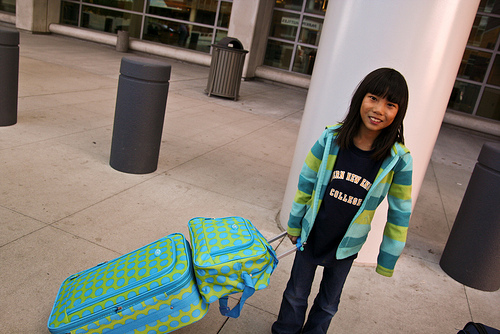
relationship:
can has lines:
[205, 34, 245, 99] [212, 51, 241, 96]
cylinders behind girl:
[108, 57, 165, 175] [268, 65, 414, 334]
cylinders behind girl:
[437, 139, 499, 294] [268, 65, 414, 334]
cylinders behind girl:
[1, 28, 21, 126] [268, 65, 414, 334]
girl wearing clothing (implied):
[268, 65, 414, 334] [286, 124, 413, 277]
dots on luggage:
[48, 216, 278, 332] [42, 208, 311, 332]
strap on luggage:
[219, 291, 263, 323] [43, 196, 326, 332]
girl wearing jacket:
[268, 65, 414, 334] [276, 125, 434, 282]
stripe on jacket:
[385, 207, 413, 226] [287, 122, 412, 275]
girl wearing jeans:
[250, 30, 458, 332] [272, 242, 355, 332]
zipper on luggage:
[69, 278, 191, 332] [48, 230, 203, 332]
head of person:
[348, 66, 412, 151] [277, 60, 432, 331]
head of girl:
[359, 67, 408, 133] [268, 65, 414, 334]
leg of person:
[316, 270, 346, 315] [330, 72, 418, 201]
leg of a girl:
[264, 260, 400, 313] [268, 65, 414, 334]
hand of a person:
[287, 235, 298, 243] [269, 69, 417, 331]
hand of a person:
[286, 234, 297, 244] [280, 185, 315, 293]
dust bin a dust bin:
[204, 37, 251, 101] [94, 45, 187, 203]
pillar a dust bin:
[105, 54, 171, 177] [204, 37, 251, 101]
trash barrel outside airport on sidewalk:
[203, 35, 250, 97] [1, 13, 496, 331]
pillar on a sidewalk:
[80, 47, 203, 207] [80, 183, 174, 213]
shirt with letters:
[306, 136, 382, 250] [330, 168, 371, 209]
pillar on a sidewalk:
[274, 1, 481, 267] [67, 169, 220, 259]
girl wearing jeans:
[268, 65, 414, 334] [269, 245, 359, 334]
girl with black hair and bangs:
[268, 65, 414, 334] [364, 70, 401, 106]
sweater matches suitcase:
[285, 124, 415, 279] [47, 214, 302, 331]